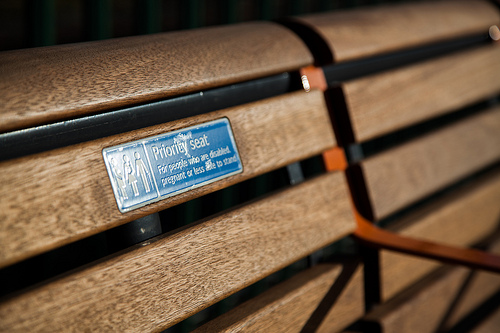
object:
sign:
[101, 117, 245, 215]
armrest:
[351, 210, 499, 276]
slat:
[299, 1, 499, 63]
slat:
[471, 315, 500, 333]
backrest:
[0, 1, 499, 332]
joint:
[273, 19, 388, 331]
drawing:
[108, 151, 152, 201]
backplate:
[0, 4, 498, 332]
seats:
[0, 0, 498, 332]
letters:
[201, 132, 209, 147]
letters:
[150, 145, 158, 161]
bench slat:
[0, 169, 358, 333]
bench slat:
[0, 20, 312, 134]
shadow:
[301, 254, 363, 332]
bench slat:
[191, 260, 364, 332]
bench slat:
[342, 42, 499, 146]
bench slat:
[381, 181, 499, 299]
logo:
[110, 152, 151, 201]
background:
[0, 0, 499, 332]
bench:
[0, 0, 498, 332]